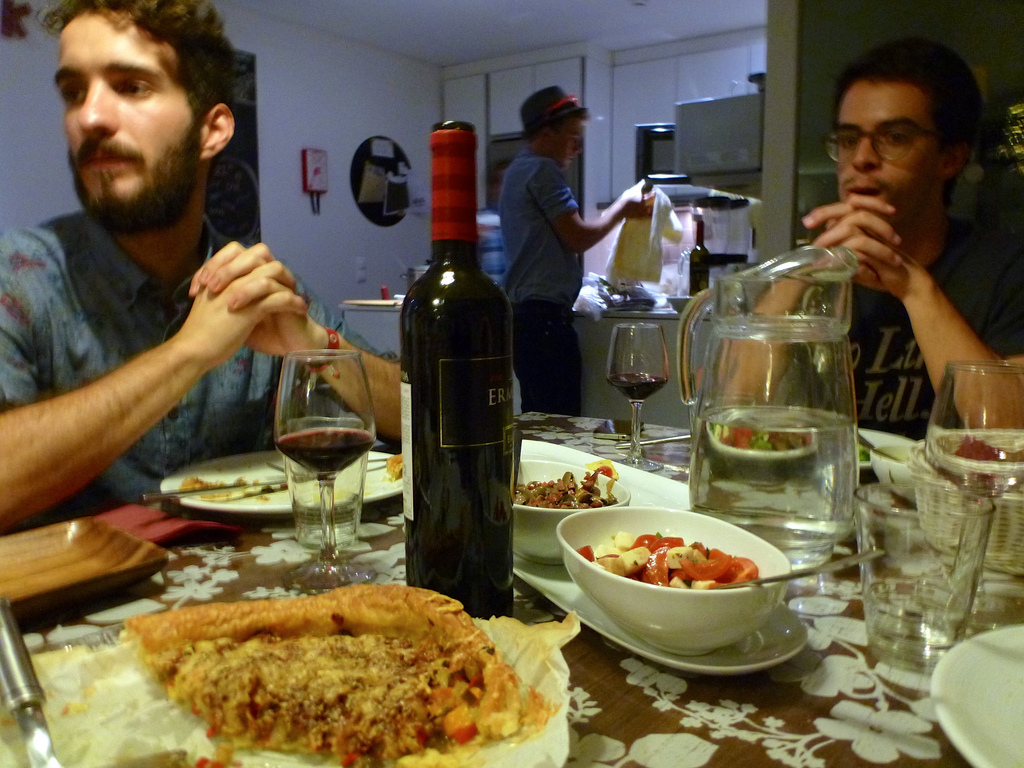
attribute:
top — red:
[433, 134, 488, 241]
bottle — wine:
[404, 119, 500, 601]